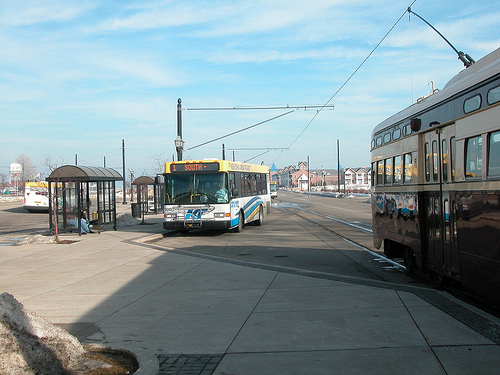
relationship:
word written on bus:
[174, 159, 210, 173] [156, 154, 278, 232]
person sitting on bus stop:
[71, 207, 96, 237] [38, 156, 130, 245]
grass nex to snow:
[86, 347, 130, 374] [24, 314, 81, 354]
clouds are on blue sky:
[0, 0, 500, 182] [0, 0, 498, 187]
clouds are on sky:
[0, 0, 500, 182] [0, 0, 498, 185]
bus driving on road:
[362, 47, 499, 340] [292, 195, 369, 247]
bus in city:
[369, 47, 500, 302] [0, 24, 492, 373]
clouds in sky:
[0, 0, 500, 182] [78, 22, 243, 131]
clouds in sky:
[0, 0, 497, 181] [0, 0, 498, 185]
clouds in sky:
[0, 0, 500, 182] [142, 24, 434, 81]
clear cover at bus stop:
[53, 182, 83, 212] [20, 150, 370, 373]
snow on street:
[341, 237, 406, 273] [0, 187, 498, 374]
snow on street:
[340, 218, 372, 232] [0, 187, 498, 374]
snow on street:
[270, 200, 307, 210] [0, 187, 498, 374]